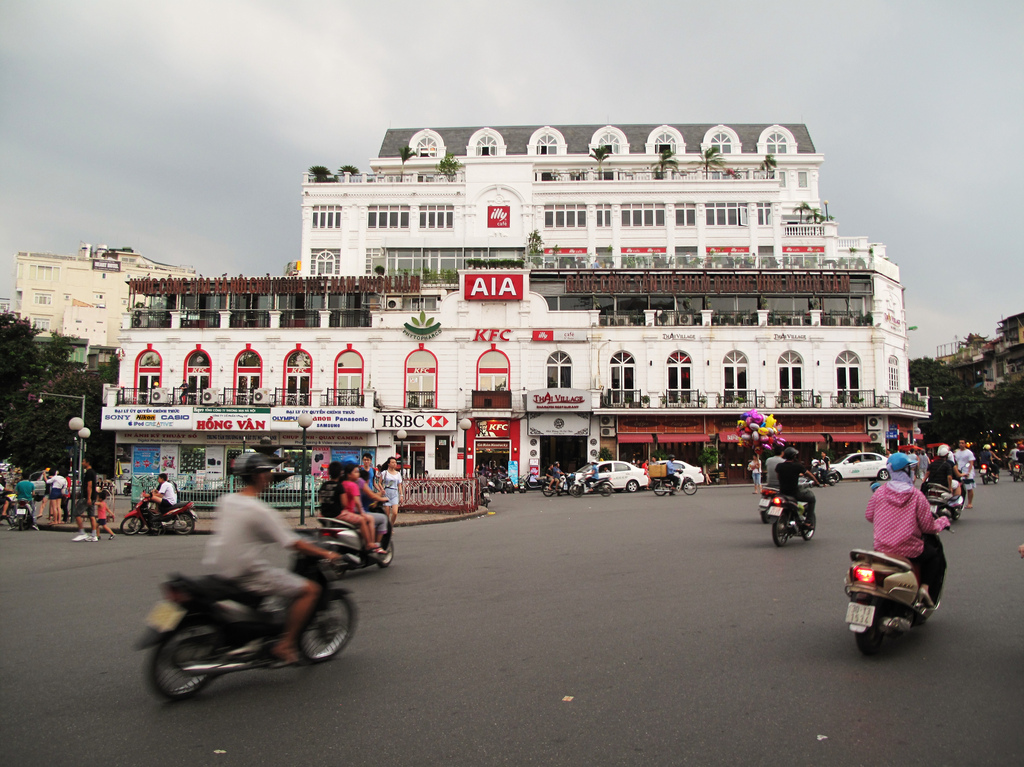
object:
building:
[101, 124, 928, 490]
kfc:
[473, 328, 511, 341]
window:
[476, 349, 509, 391]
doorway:
[466, 417, 520, 482]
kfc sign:
[476, 419, 511, 437]